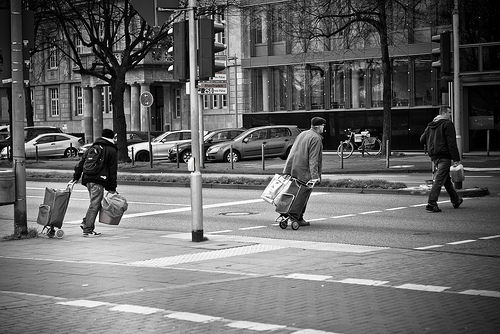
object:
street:
[155, 262, 338, 299]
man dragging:
[275, 180, 319, 231]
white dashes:
[278, 272, 500, 300]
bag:
[98, 191, 129, 226]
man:
[71, 127, 121, 237]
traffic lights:
[165, 17, 227, 83]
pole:
[187, 0, 204, 244]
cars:
[127, 127, 246, 162]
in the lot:
[0, 114, 155, 161]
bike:
[337, 128, 383, 160]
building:
[235, 0, 456, 152]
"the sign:
[139, 90, 154, 108]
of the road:
[130, 189, 185, 228]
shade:
[313, 224, 424, 234]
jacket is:
[73, 136, 120, 192]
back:
[81, 140, 109, 181]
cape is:
[101, 128, 121, 146]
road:
[205, 192, 260, 228]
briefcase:
[37, 178, 79, 240]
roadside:
[318, 131, 472, 165]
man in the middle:
[280, 116, 326, 226]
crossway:
[358, 174, 409, 241]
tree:
[245, 0, 438, 157]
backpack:
[83, 145, 106, 176]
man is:
[425, 159, 463, 205]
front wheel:
[224, 151, 242, 163]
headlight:
[208, 145, 223, 154]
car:
[206, 125, 303, 163]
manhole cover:
[221, 211, 254, 216]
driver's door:
[242, 129, 269, 158]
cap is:
[310, 116, 326, 126]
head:
[311, 116, 326, 133]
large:
[259, 173, 292, 205]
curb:
[340, 156, 416, 168]